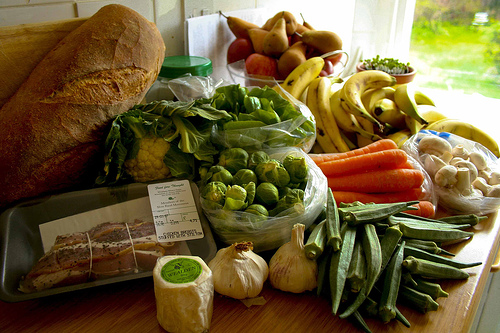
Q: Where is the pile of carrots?
A: On the counter.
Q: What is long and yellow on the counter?
A: The pile of bananas.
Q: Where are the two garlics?
A: On the table.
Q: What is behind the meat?
A: The loaf of bread.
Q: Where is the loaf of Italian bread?
A: On the counter.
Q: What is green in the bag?
A: Fresh brussel sprouts.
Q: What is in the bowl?
A: Fresh pears and apples.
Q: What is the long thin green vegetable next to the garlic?
A: Okra.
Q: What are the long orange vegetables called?
A: Carrots.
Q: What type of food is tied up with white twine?
A: Meat.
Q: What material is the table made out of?
A: Wood.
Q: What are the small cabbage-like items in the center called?
A: Brussel sprouts.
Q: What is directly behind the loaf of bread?
A: Cutting board.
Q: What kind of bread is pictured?
A: Italian.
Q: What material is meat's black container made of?
A: Styrofoam.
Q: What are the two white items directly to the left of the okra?
A: Garlic.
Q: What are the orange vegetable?
A: Carrots.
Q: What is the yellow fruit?
A: Bananas.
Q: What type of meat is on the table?
A: Bacon.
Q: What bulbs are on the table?
A: Garlic bulbs.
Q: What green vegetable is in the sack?
A: Brussel sprouts.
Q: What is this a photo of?
A: Fruits and vegetables.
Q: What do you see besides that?
A: A loaf of bread.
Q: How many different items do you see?
A: At least twelve.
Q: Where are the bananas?
A: Behind the carrots.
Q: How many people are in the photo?
A: None.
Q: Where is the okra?
A: In the front.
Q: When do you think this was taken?
A: During the day.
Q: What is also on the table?
A: A sign of some sort.